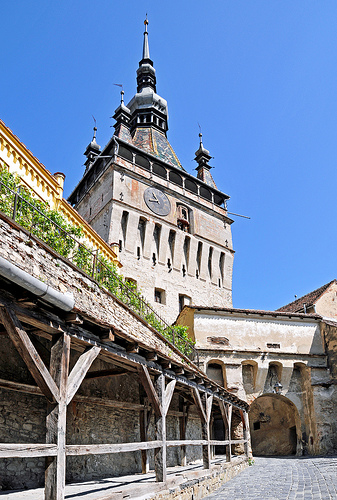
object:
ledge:
[23, 158, 122, 254]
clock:
[144, 187, 171, 217]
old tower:
[63, 9, 235, 324]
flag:
[142, 8, 150, 58]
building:
[65, 9, 238, 325]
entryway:
[246, 392, 302, 458]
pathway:
[238, 448, 336, 499]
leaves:
[0, 169, 9, 194]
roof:
[0, 212, 250, 414]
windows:
[154, 287, 166, 305]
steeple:
[109, 82, 133, 145]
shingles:
[29, 253, 65, 273]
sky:
[231, 5, 336, 268]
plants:
[0, 162, 83, 274]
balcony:
[0, 167, 199, 372]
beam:
[1, 302, 250, 500]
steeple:
[191, 118, 221, 188]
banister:
[149, 159, 155, 173]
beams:
[112, 134, 233, 212]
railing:
[0, 181, 199, 369]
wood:
[5, 313, 61, 408]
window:
[175, 200, 194, 235]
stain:
[131, 179, 139, 203]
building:
[0, 118, 199, 484]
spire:
[110, 82, 133, 144]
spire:
[81, 115, 102, 175]